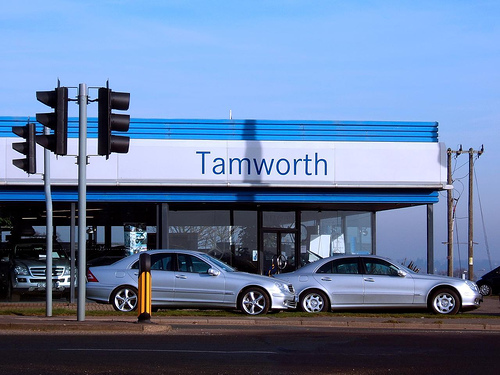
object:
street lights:
[29, 132, 61, 155]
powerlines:
[440, 145, 457, 279]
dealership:
[1, 115, 453, 287]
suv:
[5, 235, 77, 298]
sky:
[1, 0, 498, 262]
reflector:
[134, 269, 152, 322]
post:
[133, 252, 155, 323]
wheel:
[237, 285, 271, 316]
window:
[176, 257, 210, 274]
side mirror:
[206, 268, 216, 276]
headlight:
[276, 282, 286, 294]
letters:
[194, 150, 211, 175]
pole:
[73, 84, 88, 321]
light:
[103, 132, 131, 153]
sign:
[137, 253, 153, 322]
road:
[0, 313, 498, 375]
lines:
[52, 345, 276, 356]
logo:
[195, 149, 329, 180]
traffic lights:
[33, 80, 75, 157]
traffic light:
[8, 123, 35, 175]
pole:
[40, 127, 56, 317]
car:
[270, 252, 481, 310]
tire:
[110, 285, 141, 312]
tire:
[297, 288, 328, 314]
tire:
[429, 286, 459, 315]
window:
[256, 206, 297, 233]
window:
[299, 209, 375, 265]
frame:
[157, 202, 264, 277]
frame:
[255, 207, 301, 236]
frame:
[291, 202, 379, 269]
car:
[84, 248, 297, 317]